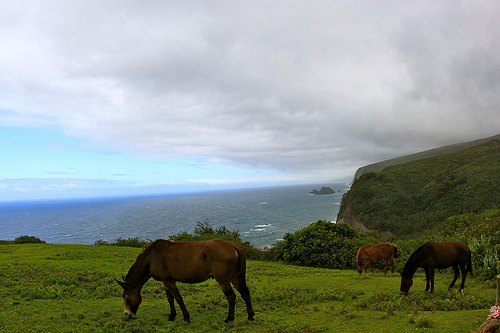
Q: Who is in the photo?
A: Nobody.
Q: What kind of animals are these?
A: Donkeys.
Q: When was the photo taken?
A: Daytime.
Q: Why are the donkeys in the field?
A: They're eating.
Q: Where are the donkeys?
A: In a field.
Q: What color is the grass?
A: Green.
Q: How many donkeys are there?
A: Three.